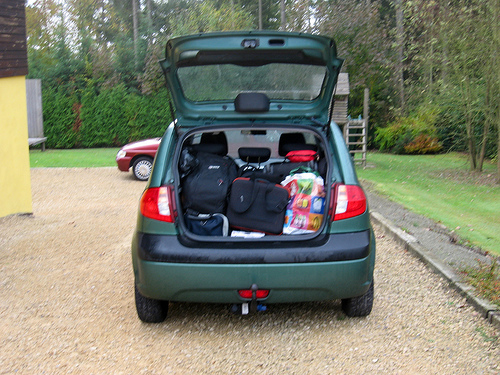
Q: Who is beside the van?
A: No one.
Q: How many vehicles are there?
A: Two.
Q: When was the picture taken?
A: Daytime.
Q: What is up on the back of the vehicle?
A: Door.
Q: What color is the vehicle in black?
A: Green.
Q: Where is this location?
A: Driveway.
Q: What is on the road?
A: Gravel.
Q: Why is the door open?
A: To unload.